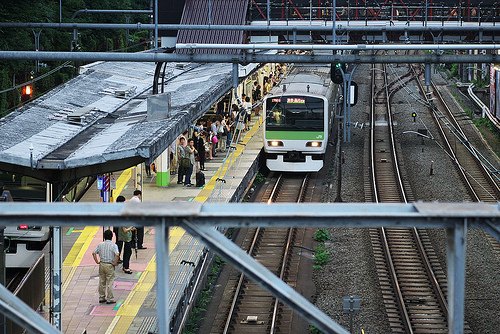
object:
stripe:
[265, 131, 324, 141]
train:
[262, 49, 337, 173]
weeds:
[312, 226, 333, 242]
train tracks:
[223, 173, 309, 334]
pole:
[156, 149, 169, 187]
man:
[92, 229, 121, 304]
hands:
[96, 262, 100, 265]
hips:
[103, 262, 114, 274]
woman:
[119, 226, 134, 275]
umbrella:
[133, 227, 139, 262]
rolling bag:
[195, 159, 206, 188]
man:
[184, 138, 198, 187]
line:
[59, 165, 135, 297]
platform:
[0, 44, 298, 332]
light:
[267, 140, 285, 148]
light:
[305, 141, 321, 148]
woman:
[207, 121, 215, 160]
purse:
[211, 136, 218, 144]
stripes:
[103, 175, 109, 182]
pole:
[103, 171, 112, 242]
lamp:
[25, 85, 31, 95]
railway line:
[367, 45, 500, 333]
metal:
[1, 200, 500, 228]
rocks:
[334, 264, 363, 288]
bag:
[180, 157, 191, 168]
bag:
[195, 170, 205, 187]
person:
[176, 137, 187, 184]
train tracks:
[360, 51, 470, 334]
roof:
[0, 39, 281, 183]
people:
[197, 131, 208, 171]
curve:
[387, 62, 420, 98]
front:
[262, 95, 329, 172]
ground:
[0, 107, 264, 334]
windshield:
[265, 95, 324, 131]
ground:
[185, 48, 499, 334]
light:
[336, 63, 341, 68]